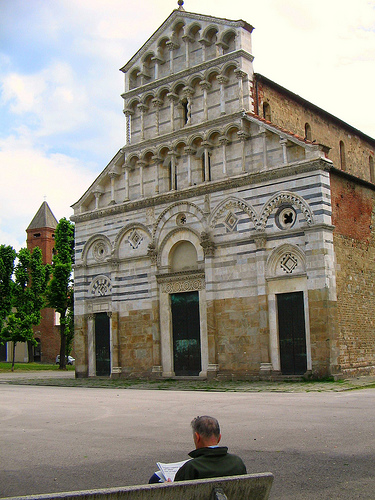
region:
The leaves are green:
[14, 263, 125, 353]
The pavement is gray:
[28, 380, 120, 491]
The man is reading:
[107, 428, 217, 482]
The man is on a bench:
[90, 410, 270, 497]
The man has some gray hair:
[175, 403, 242, 461]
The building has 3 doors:
[68, 266, 345, 413]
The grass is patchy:
[238, 359, 371, 422]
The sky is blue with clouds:
[11, 97, 161, 228]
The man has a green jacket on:
[160, 445, 248, 480]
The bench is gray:
[187, 468, 271, 498]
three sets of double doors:
[76, 291, 351, 389]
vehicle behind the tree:
[50, 342, 81, 371]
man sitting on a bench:
[164, 422, 257, 492]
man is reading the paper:
[148, 409, 230, 480]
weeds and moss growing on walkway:
[103, 374, 327, 392]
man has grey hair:
[178, 404, 261, 451]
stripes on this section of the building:
[65, 185, 372, 305]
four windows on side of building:
[257, 98, 373, 182]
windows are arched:
[261, 101, 374, 173]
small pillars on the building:
[73, 33, 308, 223]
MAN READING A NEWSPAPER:
[138, 459, 223, 484]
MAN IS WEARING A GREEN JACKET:
[182, 435, 236, 475]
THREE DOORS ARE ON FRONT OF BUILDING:
[73, 301, 357, 376]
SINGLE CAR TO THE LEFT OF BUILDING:
[47, 346, 91, 366]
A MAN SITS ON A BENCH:
[138, 400, 238, 498]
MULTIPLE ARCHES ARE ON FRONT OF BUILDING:
[76, 194, 370, 290]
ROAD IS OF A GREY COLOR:
[6, 389, 370, 496]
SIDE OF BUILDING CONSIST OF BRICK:
[249, 87, 371, 325]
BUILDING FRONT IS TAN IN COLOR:
[39, 182, 345, 370]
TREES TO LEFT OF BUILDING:
[4, 216, 70, 359]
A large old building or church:
[0, 0, 371, 386]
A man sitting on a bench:
[138, 405, 250, 495]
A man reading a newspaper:
[152, 408, 253, 476]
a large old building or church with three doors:
[69, 15, 328, 379]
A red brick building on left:
[23, 196, 61, 370]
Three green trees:
[2, 219, 70, 370]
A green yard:
[5, 356, 76, 375]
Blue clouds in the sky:
[2, 4, 373, 223]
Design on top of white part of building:
[72, 3, 312, 214]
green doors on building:
[80, 295, 336, 373]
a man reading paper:
[176, 458, 201, 484]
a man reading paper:
[162, 427, 240, 492]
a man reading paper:
[117, 370, 192, 453]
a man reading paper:
[145, 413, 212, 492]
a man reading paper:
[133, 435, 198, 491]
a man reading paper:
[170, 367, 230, 485]